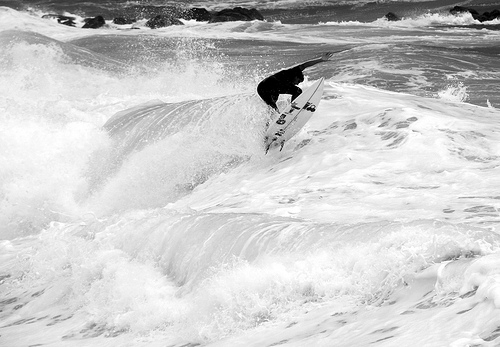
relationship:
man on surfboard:
[254, 45, 334, 110] [256, 76, 330, 153]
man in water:
[256, 47, 334, 110] [0, 1, 499, 345]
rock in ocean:
[82, 12, 107, 24] [3, 3, 498, 333]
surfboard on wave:
[264, 77, 329, 155] [99, 83, 494, 314]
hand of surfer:
[318, 46, 343, 65] [255, 50, 325, 151]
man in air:
[256, 47, 334, 110] [393, 11, 396, 20]